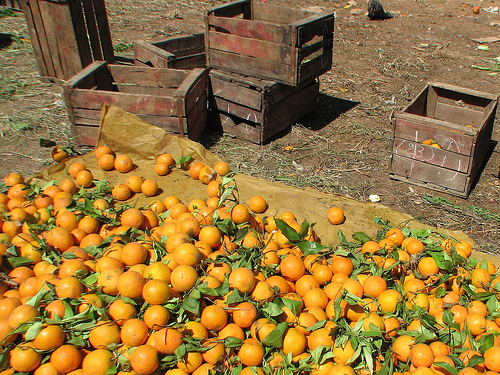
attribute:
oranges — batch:
[46, 190, 483, 364]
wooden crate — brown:
[191, 1, 344, 90]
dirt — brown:
[1, 0, 498, 259]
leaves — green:
[1, 145, 499, 372]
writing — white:
[393, 129, 462, 182]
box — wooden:
[385, 79, 499, 200]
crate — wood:
[205, 60, 323, 142]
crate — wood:
[129, 26, 215, 103]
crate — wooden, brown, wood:
[59, 60, 214, 147]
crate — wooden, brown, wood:
[18, 0, 114, 88]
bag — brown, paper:
[6, 104, 496, 261]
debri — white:
[368, 191, 380, 203]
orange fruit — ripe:
[140, 177, 159, 195]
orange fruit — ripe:
[113, 152, 133, 173]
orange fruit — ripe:
[327, 206, 345, 225]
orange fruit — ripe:
[248, 195, 266, 212]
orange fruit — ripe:
[281, 254, 306, 280]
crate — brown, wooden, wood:
[383, 81, 499, 198]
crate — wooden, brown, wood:
[202, 0, 335, 87]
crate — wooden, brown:
[205, 66, 323, 146]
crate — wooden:
[62, 56, 209, 146]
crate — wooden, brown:
[130, 30, 207, 67]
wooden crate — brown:
[203, 2, 335, 89]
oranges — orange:
[107, 202, 271, 339]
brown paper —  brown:
[260, 177, 297, 207]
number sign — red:
[216, 18, 277, 58]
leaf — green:
[209, 213, 246, 244]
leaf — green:
[275, 211, 320, 250]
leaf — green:
[338, 316, 378, 348]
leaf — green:
[63, 189, 103, 218]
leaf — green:
[59, 307, 91, 334]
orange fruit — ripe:
[361, 275, 388, 297]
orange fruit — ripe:
[168, 264, 200, 291]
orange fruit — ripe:
[127, 345, 162, 372]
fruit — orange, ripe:
[287, 270, 411, 331]